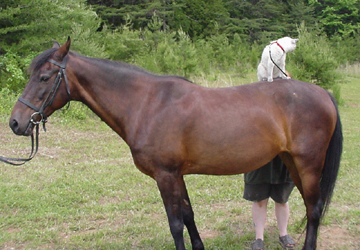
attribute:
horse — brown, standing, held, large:
[8, 35, 344, 249]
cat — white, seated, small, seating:
[256, 35, 297, 85]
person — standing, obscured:
[244, 155, 296, 249]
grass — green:
[1, 62, 358, 249]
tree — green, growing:
[170, 2, 233, 43]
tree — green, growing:
[0, 2, 109, 104]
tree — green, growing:
[92, 2, 166, 31]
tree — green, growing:
[315, 1, 359, 39]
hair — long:
[29, 45, 59, 74]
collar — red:
[275, 40, 286, 56]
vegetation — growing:
[2, 11, 357, 105]